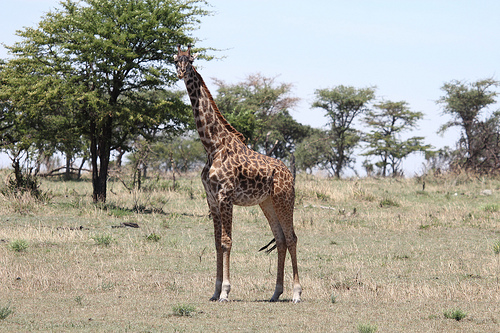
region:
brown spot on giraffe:
[184, 78, 195, 87]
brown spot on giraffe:
[188, 85, 200, 98]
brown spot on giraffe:
[189, 95, 199, 107]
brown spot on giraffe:
[194, 113, 206, 129]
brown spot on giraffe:
[203, 108, 215, 125]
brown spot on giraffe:
[202, 121, 212, 141]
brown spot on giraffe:
[224, 158, 232, 170]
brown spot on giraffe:
[238, 154, 245, 163]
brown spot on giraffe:
[278, 166, 285, 181]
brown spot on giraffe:
[246, 176, 258, 191]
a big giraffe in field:
[163, 35, 315, 310]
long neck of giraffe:
[183, 69, 235, 152]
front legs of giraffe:
[205, 203, 236, 305]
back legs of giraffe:
[266, 210, 304, 306]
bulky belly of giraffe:
[235, 170, 275, 212]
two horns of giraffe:
[171, 37, 198, 54]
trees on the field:
[0, 0, 499, 329]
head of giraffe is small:
[164, 43, 200, 83]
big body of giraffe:
[198, 145, 303, 211]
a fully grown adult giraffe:
[147, 46, 319, 311]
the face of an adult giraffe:
[162, 45, 196, 85]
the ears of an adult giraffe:
[162, 49, 200, 60]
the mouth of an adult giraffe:
[171, 62, 189, 74]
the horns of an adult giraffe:
[170, 37, 191, 48]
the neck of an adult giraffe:
[178, 83, 238, 147]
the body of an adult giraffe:
[201, 136, 309, 214]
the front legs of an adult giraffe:
[200, 202, 240, 300]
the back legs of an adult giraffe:
[250, 198, 311, 300]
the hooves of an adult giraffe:
[204, 279, 238, 300]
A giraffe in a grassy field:
[163, 38, 317, 315]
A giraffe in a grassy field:
[163, 34, 315, 312]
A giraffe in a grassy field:
[158, 37, 321, 313]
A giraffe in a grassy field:
[159, 33, 309, 313]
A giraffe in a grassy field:
[152, 37, 314, 314]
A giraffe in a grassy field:
[157, 32, 313, 313]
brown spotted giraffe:
[147, 24, 304, 284]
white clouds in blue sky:
[215, 15, 260, 67]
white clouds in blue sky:
[271, 40, 308, 64]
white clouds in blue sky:
[268, 11, 316, 45]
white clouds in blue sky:
[347, 15, 386, 55]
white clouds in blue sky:
[345, 18, 392, 80]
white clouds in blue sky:
[407, 33, 472, 88]